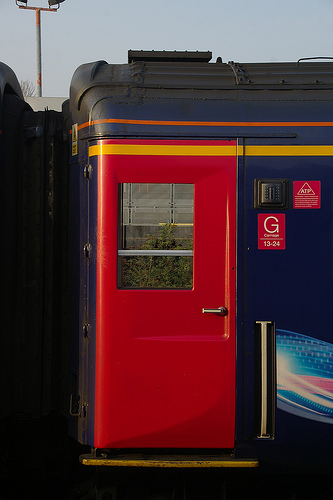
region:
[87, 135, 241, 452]
a red door on a train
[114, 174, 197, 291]
a window on a door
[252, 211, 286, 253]
a sign on a train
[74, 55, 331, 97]
the roof of a train car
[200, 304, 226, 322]
a metal door handle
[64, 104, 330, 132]
an orange stripe on a train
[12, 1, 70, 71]
flood lights on a pole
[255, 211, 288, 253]
a red sign with white letters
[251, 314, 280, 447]
a handle on a train car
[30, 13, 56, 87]
a white and orange pole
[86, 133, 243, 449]
Egress door on train car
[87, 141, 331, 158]
Painted yellow stripe on train car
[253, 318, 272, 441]
Metal hand support rail on train car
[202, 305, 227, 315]
Metal lever door handle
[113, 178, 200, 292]
Window on train car door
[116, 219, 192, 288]
Evergreen tree reflected in window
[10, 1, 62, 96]
Metal support pole for lights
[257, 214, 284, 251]
Train car identification label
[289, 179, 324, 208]
Train car information label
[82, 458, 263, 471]
Support step below train car door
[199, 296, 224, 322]
There is a door handle that is visible here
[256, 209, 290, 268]
There is a G letter that is visible here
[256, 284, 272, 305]
There is a blue color on the train here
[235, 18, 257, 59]
There is a light blue sky that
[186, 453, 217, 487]
There is a yellow platform here that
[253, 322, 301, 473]
There is a silver handle on the train now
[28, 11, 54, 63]
There is a rusty lamp post here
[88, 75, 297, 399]
This photo was taken in Philadelphia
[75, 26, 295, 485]
This photo was taken in Pennsylvania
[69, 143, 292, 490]
This photo won an award for being precise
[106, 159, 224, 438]
red door on train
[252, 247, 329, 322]
train is dark blue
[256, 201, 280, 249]
red and white sign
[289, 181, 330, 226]
red and white notice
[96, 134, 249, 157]
yellow stripe on door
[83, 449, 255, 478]
small platform in front of door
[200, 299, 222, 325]
silver handle on door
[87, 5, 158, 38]
sky is grey and hazy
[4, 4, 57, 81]
tall red light pole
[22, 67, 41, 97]
bare trees behind light pole